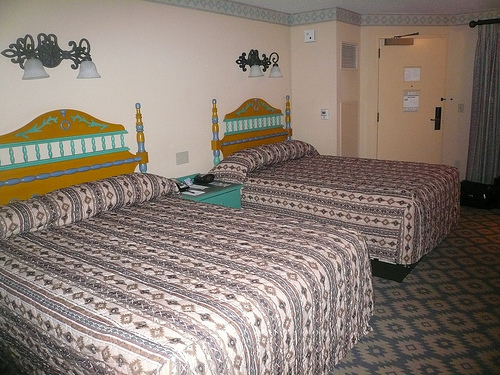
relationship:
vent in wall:
[338, 38, 361, 73] [337, 10, 364, 154]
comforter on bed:
[143, 227, 235, 292] [3, 186, 314, 330]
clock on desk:
[196, 167, 221, 191] [176, 172, 243, 212]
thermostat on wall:
[304, 103, 334, 123] [210, 47, 408, 195]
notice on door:
[390, 85, 434, 139] [350, 10, 467, 204]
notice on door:
[375, 45, 425, 90] [350, 10, 467, 204]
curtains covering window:
[465, 20, 500, 186] [443, 77, 498, 127]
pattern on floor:
[412, 317, 440, 333] [342, 257, 455, 373]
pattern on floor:
[412, 317, 440, 333] [325, 202, 498, 374]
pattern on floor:
[412, 317, 440, 333] [396, 266, 463, 371]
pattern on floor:
[398, 290, 472, 364] [431, 246, 477, 284]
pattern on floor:
[412, 317, 440, 333] [376, 278, 498, 373]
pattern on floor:
[412, 317, 440, 333] [379, 278, 483, 365]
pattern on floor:
[412, 317, 440, 333] [129, 70, 487, 337]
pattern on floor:
[412, 317, 440, 333] [352, 192, 499, 370]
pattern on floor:
[412, 317, 440, 333] [331, 180, 498, 370]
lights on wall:
[235, 35, 295, 80] [124, 19, 314, 131]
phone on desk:
[167, 176, 189, 194] [169, 172, 242, 210]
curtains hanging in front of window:
[465, 39, 499, 186] [479, 78, 485, 98]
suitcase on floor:
[460, 179, 497, 206] [325, 202, 498, 374]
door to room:
[359, 30, 484, 178] [2, 0, 497, 371]